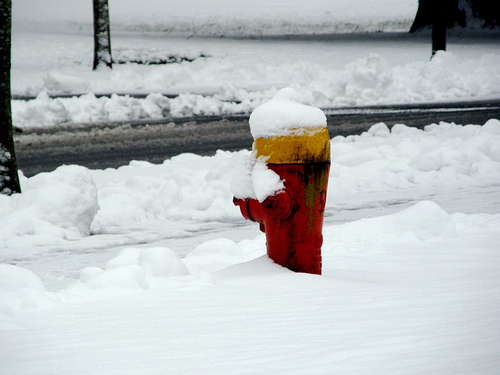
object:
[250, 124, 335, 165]
top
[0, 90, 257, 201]
snow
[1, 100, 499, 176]
road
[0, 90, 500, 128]
sidewalk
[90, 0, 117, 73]
trunk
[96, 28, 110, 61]
snow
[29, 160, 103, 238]
snowball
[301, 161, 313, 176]
stains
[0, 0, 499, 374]
ground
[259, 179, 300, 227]
nozzle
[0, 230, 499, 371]
snow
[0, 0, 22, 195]
trees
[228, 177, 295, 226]
hose attachment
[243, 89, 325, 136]
snow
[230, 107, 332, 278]
fire hydrant